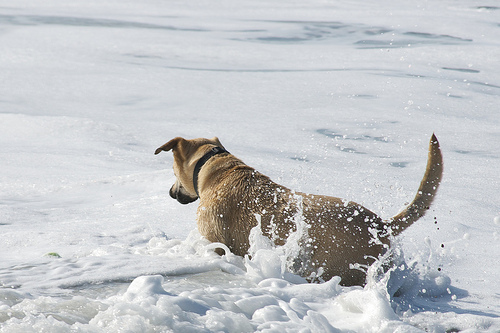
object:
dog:
[154, 132, 444, 290]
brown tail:
[382, 131, 445, 236]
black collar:
[192, 147, 228, 199]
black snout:
[168, 187, 189, 205]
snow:
[0, 0, 500, 333]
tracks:
[0, 0, 499, 99]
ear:
[154, 137, 182, 156]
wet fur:
[239, 201, 329, 243]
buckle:
[211, 146, 224, 153]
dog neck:
[188, 143, 235, 196]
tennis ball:
[48, 252, 62, 257]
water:
[0, 291, 428, 332]